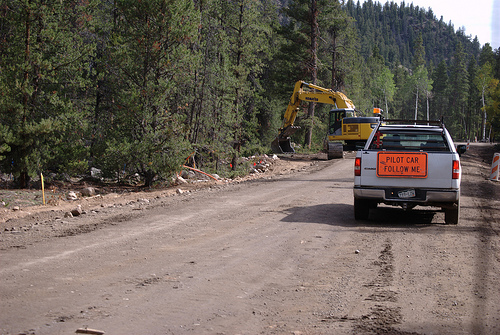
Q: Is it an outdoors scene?
A: Yes, it is outdoors.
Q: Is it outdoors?
A: Yes, it is outdoors.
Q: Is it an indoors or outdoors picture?
A: It is outdoors.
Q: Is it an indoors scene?
A: No, it is outdoors.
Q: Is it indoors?
A: No, it is outdoors.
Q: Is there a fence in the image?
A: No, there are no fences.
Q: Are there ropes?
A: No, there are no ropes.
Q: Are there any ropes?
A: No, there are no ropes.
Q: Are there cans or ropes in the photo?
A: No, there are no ropes or cans.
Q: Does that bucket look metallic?
A: Yes, the bucket is metallic.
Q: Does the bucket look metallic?
A: Yes, the bucket is metallic.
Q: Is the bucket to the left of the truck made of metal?
A: Yes, the bucket is made of metal.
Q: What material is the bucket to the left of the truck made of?
A: The bucket is made of metal.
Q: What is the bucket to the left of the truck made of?
A: The bucket is made of metal.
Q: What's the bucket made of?
A: The bucket is made of metal.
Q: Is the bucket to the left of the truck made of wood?
A: No, the bucket is made of metal.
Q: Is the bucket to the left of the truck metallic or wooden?
A: The bucket is metallic.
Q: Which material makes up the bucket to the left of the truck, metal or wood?
A: The bucket is made of metal.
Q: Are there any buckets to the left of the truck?
A: Yes, there is a bucket to the left of the truck.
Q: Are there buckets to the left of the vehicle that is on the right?
A: Yes, there is a bucket to the left of the truck.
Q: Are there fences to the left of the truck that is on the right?
A: No, there is a bucket to the left of the truck.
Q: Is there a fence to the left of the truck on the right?
A: No, there is a bucket to the left of the truck.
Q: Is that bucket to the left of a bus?
A: No, the bucket is to the left of the truck.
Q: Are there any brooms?
A: No, there are no brooms.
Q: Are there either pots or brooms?
A: No, there are no brooms or pots.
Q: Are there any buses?
A: No, there are no buses.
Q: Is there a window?
A: Yes, there is a window.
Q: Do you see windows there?
A: Yes, there is a window.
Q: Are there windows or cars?
A: Yes, there is a window.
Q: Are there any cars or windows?
A: Yes, there is a window.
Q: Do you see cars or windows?
A: Yes, there is a window.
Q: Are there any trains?
A: No, there are no trains.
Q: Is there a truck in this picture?
A: Yes, there is a truck.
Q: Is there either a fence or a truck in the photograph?
A: Yes, there is a truck.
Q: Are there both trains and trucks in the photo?
A: No, there is a truck but no trains.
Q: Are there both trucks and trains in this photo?
A: No, there is a truck but no trains.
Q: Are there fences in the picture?
A: No, there are no fences.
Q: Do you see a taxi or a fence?
A: No, there are no fences or taxis.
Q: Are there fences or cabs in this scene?
A: No, there are no fences or cabs.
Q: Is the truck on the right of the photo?
A: Yes, the truck is on the right of the image.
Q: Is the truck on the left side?
A: No, the truck is on the right of the image.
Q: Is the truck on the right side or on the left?
A: The truck is on the right of the image.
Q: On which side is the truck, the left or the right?
A: The truck is on the right of the image.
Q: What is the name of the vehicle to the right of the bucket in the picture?
A: The vehicle is a truck.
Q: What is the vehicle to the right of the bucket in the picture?
A: The vehicle is a truck.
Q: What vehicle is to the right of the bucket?
A: The vehicle is a truck.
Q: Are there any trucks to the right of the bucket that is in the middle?
A: Yes, there is a truck to the right of the bucket.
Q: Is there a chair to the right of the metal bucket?
A: No, there is a truck to the right of the bucket.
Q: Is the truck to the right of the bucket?
A: Yes, the truck is to the right of the bucket.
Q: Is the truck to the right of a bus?
A: No, the truck is to the right of the bucket.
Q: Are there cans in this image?
A: No, there are no cans.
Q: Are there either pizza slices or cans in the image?
A: No, there are no cans or pizza slices.